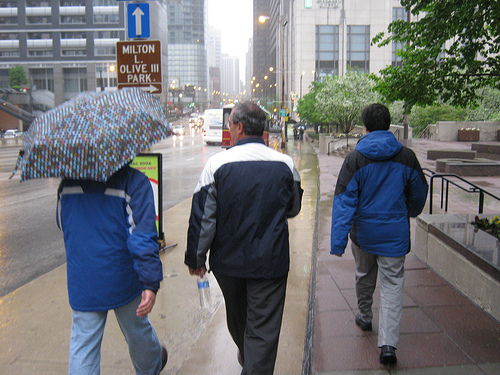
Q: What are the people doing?
A: Walking.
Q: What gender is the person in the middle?
A: Male.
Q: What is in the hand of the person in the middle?
A: Water bottle.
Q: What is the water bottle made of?
A: Plastic.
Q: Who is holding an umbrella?
A: Person on left.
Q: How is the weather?
A: Raining.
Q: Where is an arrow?
A: On a sign.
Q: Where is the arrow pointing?
A: Up.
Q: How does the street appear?
A: Wet.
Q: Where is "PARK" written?
A: On a red sign.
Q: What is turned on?
A: Street lights.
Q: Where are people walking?
A: On the sidewalk.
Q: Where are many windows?
A: On buildings.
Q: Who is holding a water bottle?
A: Man in the middle.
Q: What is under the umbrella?
A: A man.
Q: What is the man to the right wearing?
A: A blue and black jacket.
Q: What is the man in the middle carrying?
A: Water.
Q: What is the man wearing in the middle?
A: A black and white jacket.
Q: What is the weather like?
A: Rainy.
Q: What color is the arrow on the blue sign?
A: White.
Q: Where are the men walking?
A: Sidewalk.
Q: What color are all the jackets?
A: Blue.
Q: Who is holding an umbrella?
A: A man.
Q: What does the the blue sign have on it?
A: An arrow.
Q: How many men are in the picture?
A: Three.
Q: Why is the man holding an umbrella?
A: Raining.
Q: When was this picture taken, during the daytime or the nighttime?
A: Daytime.